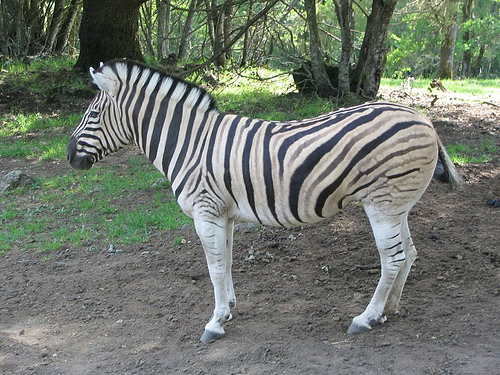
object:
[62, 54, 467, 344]
zebra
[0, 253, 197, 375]
dirt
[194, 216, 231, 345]
leg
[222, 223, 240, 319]
leg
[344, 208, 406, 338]
leg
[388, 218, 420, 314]
leg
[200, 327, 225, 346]
hoof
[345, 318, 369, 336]
hoof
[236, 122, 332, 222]
stripe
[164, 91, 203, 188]
stripe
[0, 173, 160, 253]
grass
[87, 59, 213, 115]
mane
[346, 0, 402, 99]
tree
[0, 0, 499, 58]
background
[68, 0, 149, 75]
tree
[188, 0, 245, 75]
tree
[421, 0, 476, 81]
tree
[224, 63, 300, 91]
sun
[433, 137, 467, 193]
tail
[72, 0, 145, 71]
trunk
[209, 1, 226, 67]
trunk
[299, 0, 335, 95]
trunk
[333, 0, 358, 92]
trunk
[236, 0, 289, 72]
branches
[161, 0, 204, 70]
branches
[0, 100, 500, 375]
shade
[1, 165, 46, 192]
rock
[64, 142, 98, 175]
nose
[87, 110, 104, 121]
eye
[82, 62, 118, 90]
ear